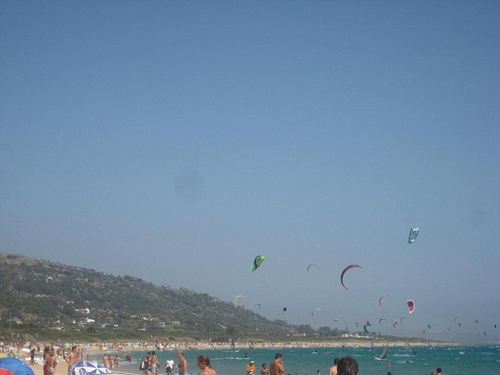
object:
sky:
[0, 0, 500, 258]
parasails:
[233, 225, 498, 348]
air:
[0, 0, 499, 375]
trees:
[0, 254, 428, 342]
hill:
[0, 251, 421, 341]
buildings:
[46, 301, 153, 334]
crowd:
[1, 341, 449, 374]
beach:
[2, 342, 217, 374]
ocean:
[88, 345, 500, 374]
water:
[84, 345, 500, 373]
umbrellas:
[0, 356, 35, 374]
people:
[0, 343, 448, 375]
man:
[269, 353, 286, 375]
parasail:
[391, 319, 399, 328]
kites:
[233, 292, 322, 321]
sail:
[374, 342, 390, 361]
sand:
[2, 340, 465, 375]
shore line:
[0, 341, 456, 374]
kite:
[340, 264, 363, 291]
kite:
[251, 254, 267, 272]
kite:
[408, 228, 421, 244]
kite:
[405, 299, 415, 314]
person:
[165, 357, 174, 374]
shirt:
[164, 360, 175, 369]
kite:
[307, 264, 320, 274]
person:
[336, 356, 359, 375]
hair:
[337, 356, 358, 375]